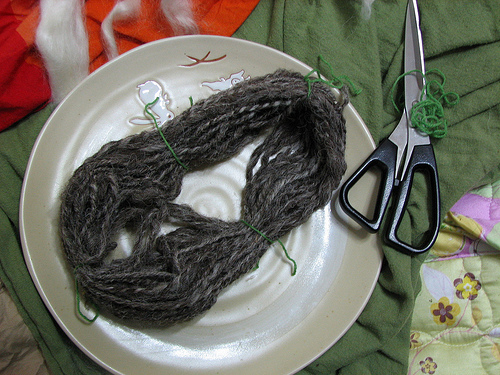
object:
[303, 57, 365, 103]
yarn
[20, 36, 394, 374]
plate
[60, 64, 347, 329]
thread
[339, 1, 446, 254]
scissors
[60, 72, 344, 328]
fabric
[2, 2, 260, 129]
hair